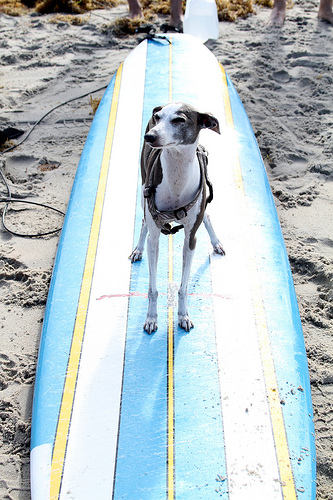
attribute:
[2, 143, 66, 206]
dips — small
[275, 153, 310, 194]
dips — small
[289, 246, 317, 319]
dips — small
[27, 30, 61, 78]
dips — small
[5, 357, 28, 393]
dips — small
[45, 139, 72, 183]
dips — small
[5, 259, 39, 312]
dips — small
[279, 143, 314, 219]
dips — small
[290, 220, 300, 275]
dips — small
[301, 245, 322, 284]
dips — small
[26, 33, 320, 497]
surfboard — white, yellow, blue, blue, yellow, and white striped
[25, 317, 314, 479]
stripes — blue, yellow, black, white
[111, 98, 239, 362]
dog — black and white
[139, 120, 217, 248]
clothing — brown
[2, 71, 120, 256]
cord — long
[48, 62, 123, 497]
stripes — yellow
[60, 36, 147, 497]
stripes — white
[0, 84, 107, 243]
cord — black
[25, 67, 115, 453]
stripes — blue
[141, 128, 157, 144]
nose — black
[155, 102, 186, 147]
spot — white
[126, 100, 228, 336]
dog — yellow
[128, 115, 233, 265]
dog — sand-surfing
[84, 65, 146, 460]
lines — white, yellow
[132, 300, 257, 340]
paws — skinny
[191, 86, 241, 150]
ear — floppy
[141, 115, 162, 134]
nose — black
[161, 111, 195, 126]
eye — black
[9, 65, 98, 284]
cord — black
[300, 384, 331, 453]
footprint — clear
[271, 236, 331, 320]
footprint — clear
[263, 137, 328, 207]
footprint — messy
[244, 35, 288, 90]
footprint — messy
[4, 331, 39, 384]
footprint — messy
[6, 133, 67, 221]
footprint — messy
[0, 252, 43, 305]
footprint — messy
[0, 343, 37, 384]
footprint — messy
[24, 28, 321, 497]
board — blue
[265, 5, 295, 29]
foot — sandy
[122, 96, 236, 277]
dog — black, white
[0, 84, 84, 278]
cord — black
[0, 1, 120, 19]
seaweed — dead brown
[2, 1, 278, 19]
seaweed —  brown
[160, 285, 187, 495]
stripe — yellow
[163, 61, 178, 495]
stripe — yellow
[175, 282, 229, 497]
stripe — blue